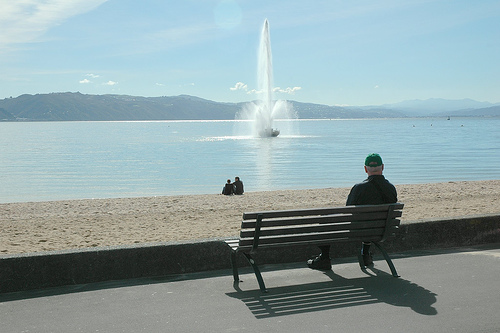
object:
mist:
[224, 18, 301, 142]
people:
[219, 178, 237, 196]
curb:
[0, 213, 499, 294]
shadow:
[224, 268, 438, 320]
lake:
[0, 115, 498, 204]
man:
[305, 152, 397, 273]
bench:
[220, 201, 406, 293]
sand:
[0, 178, 499, 256]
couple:
[220, 176, 245, 196]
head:
[360, 152, 385, 177]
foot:
[303, 249, 335, 271]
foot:
[355, 248, 375, 268]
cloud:
[0, 0, 111, 45]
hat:
[363, 152, 383, 168]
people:
[230, 176, 245, 196]